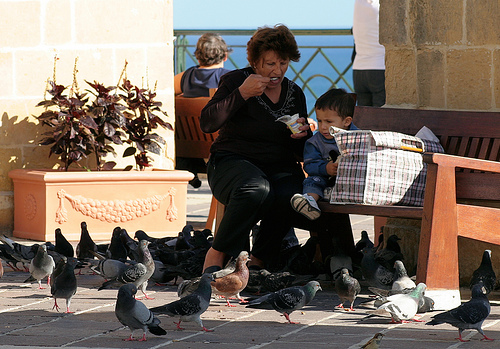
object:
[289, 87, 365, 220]
person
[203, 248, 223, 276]
feet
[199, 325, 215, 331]
feet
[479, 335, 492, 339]
feet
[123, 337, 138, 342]
feet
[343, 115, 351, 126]
ear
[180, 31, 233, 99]
man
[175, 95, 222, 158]
bench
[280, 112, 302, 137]
yogurt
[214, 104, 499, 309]
bench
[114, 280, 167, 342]
pigeon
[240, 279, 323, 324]
pigeon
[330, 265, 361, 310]
pigeon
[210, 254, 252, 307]
pigeon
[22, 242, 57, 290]
pigeon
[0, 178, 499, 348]
ground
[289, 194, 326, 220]
feet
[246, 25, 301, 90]
head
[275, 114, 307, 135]
cup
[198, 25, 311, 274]
person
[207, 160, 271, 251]
leg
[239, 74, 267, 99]
hand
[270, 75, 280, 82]
mouth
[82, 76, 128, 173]
plants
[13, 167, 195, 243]
stand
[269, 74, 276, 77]
spoon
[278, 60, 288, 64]
eye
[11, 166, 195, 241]
planter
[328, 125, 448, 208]
bag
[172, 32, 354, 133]
ocean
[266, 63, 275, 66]
eye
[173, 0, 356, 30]
sky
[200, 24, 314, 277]
they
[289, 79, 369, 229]
they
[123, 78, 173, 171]
plants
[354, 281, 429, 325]
bird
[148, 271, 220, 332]
bird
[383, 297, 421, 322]
wing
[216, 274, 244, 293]
wing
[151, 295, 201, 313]
wing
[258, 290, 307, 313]
wing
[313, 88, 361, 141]
head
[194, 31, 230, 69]
head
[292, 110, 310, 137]
hand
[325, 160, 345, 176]
hand